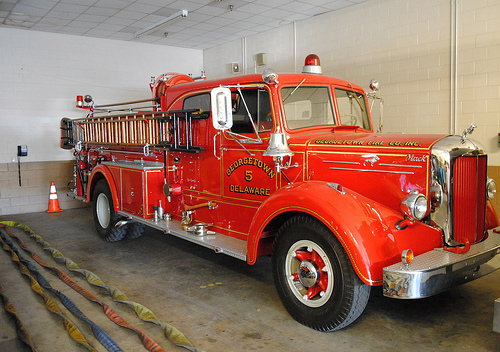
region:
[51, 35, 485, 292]
red truck in the photo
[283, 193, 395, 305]
wheel of the truck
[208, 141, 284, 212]
writing on the truck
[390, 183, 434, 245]
light on the truck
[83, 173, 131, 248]
back tire of the truck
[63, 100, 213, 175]
ladder on the truck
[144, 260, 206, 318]
ground next to truck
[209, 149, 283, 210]
words on side of truck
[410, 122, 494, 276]
front of the truck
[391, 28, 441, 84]
wall next to the truck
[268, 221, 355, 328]
it is the front tire of the truck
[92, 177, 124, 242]
it is the back tire of the truck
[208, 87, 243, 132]
left side mirror of the truck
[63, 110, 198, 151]
it is a ladder on the side of the truck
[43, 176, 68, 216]
an orange parking cone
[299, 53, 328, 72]
a red light on top of the truck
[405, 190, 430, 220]
left front side headlight of the truck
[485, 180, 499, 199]
it is the headlight of the truck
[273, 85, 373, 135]
the windshield mirror of the truck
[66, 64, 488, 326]
it is a red fire truck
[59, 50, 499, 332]
a classic fire engine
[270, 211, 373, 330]
a black front right tire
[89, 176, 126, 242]
a black rear right tire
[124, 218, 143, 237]
a black rear right tire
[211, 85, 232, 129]
a rear view mirror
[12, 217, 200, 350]
an outstretched yellow hose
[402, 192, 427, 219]
a fire engine headlight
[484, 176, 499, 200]
a fire engine headlight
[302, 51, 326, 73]
a red fire engine light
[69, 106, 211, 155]
a fire engine ladder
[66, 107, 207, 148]
Large collapsible ladder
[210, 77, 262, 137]
Large chrome side mirror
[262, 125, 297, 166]
Large silver bell on side of a firetruck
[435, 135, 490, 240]
Front grill on vintage firetruck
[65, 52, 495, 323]
A vintage era firetruck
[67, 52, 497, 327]
A old time red firetruck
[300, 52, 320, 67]
A small red strobe-light on top of a firetruck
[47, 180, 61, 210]
A orange traffic cone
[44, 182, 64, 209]
A orange traffic cone with silver stripes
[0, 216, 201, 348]
Fire-hoses laid out on the floor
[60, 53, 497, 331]
an antique fire engine in a room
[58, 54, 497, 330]
an antique fire engine in a garage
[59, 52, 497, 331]
a delaware fire engine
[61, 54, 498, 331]
a truck for fighting fires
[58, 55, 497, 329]
a red, yellow and silver fire truck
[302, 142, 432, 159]
yellow stripes on a fire truck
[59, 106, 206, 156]
ladder on the fire truck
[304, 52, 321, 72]
red light on the roof of the truck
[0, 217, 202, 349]
fire hoses on the floor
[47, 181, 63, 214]
a white and orange cone